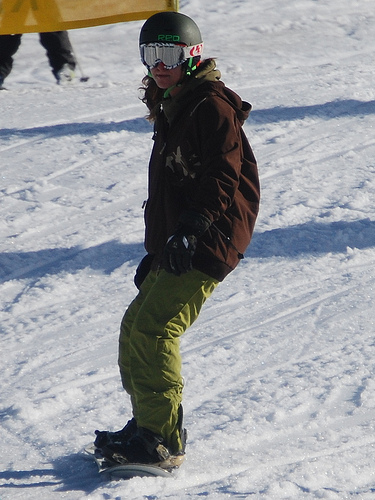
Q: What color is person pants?
A: Green.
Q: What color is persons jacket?
A: Brown.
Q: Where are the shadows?
A: In the snow.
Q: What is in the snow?
A: Tracks.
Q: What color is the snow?
A: White.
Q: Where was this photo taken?
A: On a snowy hill.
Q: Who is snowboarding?
A: A female.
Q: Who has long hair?
A: The snowboarder.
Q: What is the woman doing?
A: Snowboarding.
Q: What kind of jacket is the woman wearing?
A: Hooded ski jacket.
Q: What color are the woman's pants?
A: Green.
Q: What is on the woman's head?
A: Helmet.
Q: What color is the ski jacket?
A: Brown.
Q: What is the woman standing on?
A: Snowboard.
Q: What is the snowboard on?
A: Snow.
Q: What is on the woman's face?
A: Goggles.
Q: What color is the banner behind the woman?
A: Yellow.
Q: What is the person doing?
A: Snowboarding.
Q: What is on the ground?
A: Snow.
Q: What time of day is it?
A: Daytime.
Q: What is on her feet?
A: A snowboard.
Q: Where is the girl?
A: On a slope.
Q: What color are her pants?
A: Green.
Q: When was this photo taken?
A: In the day.